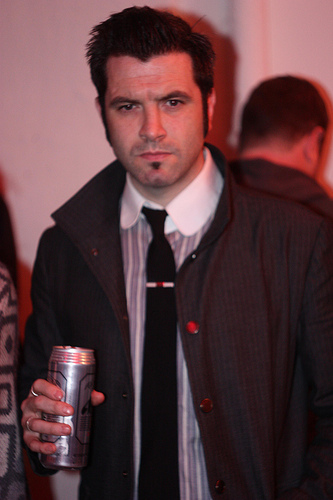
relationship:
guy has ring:
[20, 5, 331, 498] [27, 381, 37, 396]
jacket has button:
[14, 142, 332, 499] [201, 393, 217, 416]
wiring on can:
[47, 368, 70, 444] [39, 333, 97, 470]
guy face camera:
[20, 5, 331, 498] [5, 5, 331, 490]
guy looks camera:
[20, 5, 331, 498] [5, 5, 331, 490]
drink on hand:
[48, 341, 89, 470] [13, 374, 110, 456]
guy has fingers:
[20, 5, 331, 498] [18, 376, 74, 455]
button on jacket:
[181, 309, 214, 336] [14, 142, 332, 499]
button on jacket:
[188, 382, 232, 419] [14, 142, 332, 499]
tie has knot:
[139, 206, 180, 499] [141, 206, 168, 236]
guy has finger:
[20, 5, 331, 498] [23, 374, 67, 398]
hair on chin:
[150, 160, 161, 169] [131, 161, 183, 190]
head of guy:
[76, 4, 234, 192] [20, 5, 331, 498]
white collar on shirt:
[109, 145, 225, 232] [108, 143, 235, 499]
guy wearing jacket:
[20, 5, 331, 498] [14, 142, 332, 499]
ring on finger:
[29, 381, 41, 399] [18, 374, 103, 461]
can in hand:
[37, 342, 95, 472] [12, 381, 107, 456]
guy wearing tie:
[20, 5, 331, 498] [128, 208, 184, 499]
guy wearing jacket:
[20, 5, 331, 498] [15, 149, 316, 488]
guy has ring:
[20, 5, 331, 498] [25, 415, 34, 429]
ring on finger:
[25, 415, 34, 429] [24, 416, 70, 436]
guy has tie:
[20, 5, 331, 498] [139, 206, 180, 499]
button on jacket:
[186, 317, 199, 336] [14, 142, 332, 499]